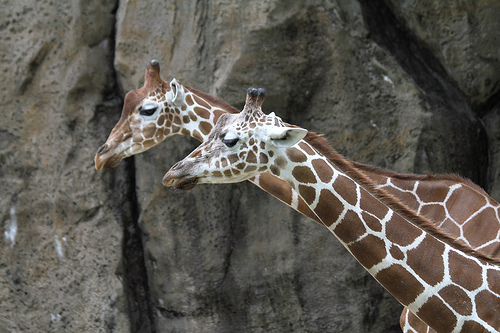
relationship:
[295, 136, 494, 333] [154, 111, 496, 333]
neck of giraffe